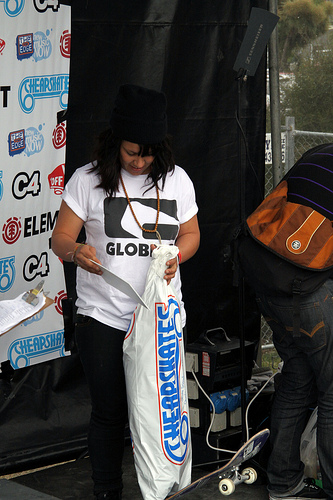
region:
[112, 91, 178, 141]
The person is wearing a black cap.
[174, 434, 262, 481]
Skateboard on the ground.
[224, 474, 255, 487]
The skateboard has white wheels.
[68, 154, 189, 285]
The person is holding a shopping bag.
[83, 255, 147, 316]
The person has a piece of paper in her hand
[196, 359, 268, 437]
A white cord hanging from the object.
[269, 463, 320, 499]
The sneakers are black.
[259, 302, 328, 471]
The person is wearing a pair of jeans.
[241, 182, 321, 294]
The bag is black and brown.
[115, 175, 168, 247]
The person has a necklace around her neck.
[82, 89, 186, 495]
person looking down at paper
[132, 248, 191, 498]
left hand holding white bag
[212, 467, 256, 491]
two white wheels on board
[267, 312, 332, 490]
person with back toward him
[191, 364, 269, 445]
wires hanging from electrical equipment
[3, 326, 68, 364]
emblem on the side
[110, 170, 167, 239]
necklace worn around the neck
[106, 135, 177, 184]
hair is long on person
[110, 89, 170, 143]
person wearing a black hat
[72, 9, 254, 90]
curtain in back is black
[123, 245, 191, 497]
white bag with blue letters on it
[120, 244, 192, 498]
white bag in the hands of the woman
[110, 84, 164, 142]
black hat on the woman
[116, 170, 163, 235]
brown necklace on the woman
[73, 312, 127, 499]
black pants on the woman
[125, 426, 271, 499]
skateboard under the white bag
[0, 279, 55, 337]
clip board with papers on it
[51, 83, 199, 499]
woman holding a white bag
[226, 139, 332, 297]
back pack on the person bending over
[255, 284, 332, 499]
jeans on the person bending over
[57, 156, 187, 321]
the shirt is white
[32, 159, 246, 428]
the shirt is white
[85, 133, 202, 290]
the woman is wearing a necklace